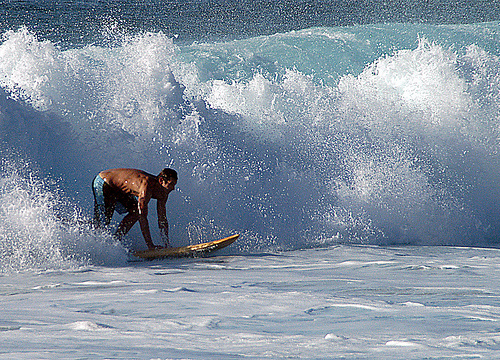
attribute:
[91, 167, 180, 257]
surfer — shirtless, surfing, tan, crouched, splashed, looking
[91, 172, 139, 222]
shorts — black, blue, wet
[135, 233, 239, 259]
surfboard — tan, curved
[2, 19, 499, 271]
wave — teal, big, breaking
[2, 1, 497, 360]
ocean — wavy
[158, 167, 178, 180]
hair — black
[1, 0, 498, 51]
water — dark blue